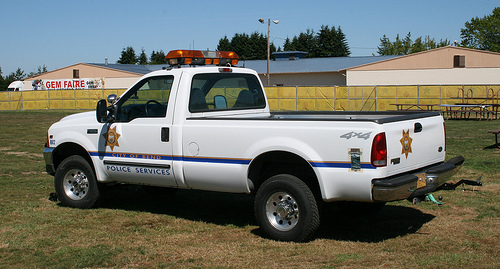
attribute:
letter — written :
[53, 80, 63, 90]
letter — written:
[39, 77, 54, 92]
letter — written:
[103, 164, 111, 172]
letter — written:
[45, 81, 51, 89]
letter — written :
[156, 163, 170, 179]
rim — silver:
[61, 167, 88, 199]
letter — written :
[164, 167, 171, 177]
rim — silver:
[258, 189, 301, 230]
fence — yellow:
[3, 87, 498, 111]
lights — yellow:
[159, 43, 241, 68]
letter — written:
[165, 170, 173, 178]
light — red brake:
[370, 129, 398, 169]